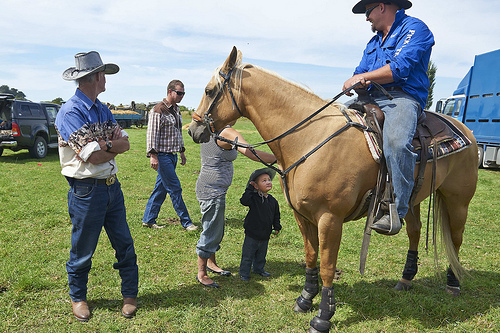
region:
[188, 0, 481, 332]
The man is on a horse.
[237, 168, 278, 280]
A boy looks up at the man.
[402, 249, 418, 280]
The horse wears leg protection.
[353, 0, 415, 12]
The man wears a hat.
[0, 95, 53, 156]
A truck is behind the people.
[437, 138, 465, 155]
The saddle pad is colorful.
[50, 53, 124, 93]
white cowboy hat on heada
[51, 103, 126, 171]
blue and white shirt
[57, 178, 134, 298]
dark blue jeans on man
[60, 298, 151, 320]
brown cowboy boots on feet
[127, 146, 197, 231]
blue jeans on man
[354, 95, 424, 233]
faded blue jeans on man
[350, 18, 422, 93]
navy blue shirt on man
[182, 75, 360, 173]
ropes on top of horse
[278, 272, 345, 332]
black padding on horse feet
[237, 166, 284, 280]
small kid looking at horse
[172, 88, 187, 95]
dark black sunglasses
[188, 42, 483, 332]
a large brown horse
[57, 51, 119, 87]
a gray cowboy hat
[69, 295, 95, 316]
part of a man's brown boot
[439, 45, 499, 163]
part of a blue truck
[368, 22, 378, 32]
a man's black beard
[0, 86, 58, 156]
part of a black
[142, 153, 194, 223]
a man's blue jean pants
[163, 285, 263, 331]
a section of green grass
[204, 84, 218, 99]
the eye of a horse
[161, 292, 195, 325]
grass on the ground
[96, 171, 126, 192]
a belt buckle on a belt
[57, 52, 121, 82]
a man wearing a hat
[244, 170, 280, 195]
a boy wearing a hat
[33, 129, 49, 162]
a tire on the truck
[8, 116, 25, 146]
a light on the truck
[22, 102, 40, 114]
a window on the truck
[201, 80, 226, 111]
the eye of a horse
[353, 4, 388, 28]
a man wearing sunglasses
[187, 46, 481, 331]
a light brown horse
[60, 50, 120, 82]
a grey cowboy hat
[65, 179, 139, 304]
a pair of blue jeans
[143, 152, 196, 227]
a pair of blue jeans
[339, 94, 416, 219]
a pair of blue jeans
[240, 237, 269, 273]
a child's pair of blue jeans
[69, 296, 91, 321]
a brown cowboy boot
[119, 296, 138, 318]
a brown cowboy boot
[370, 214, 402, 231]
a black cowboy boot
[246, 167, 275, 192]
a child's cowboy hat